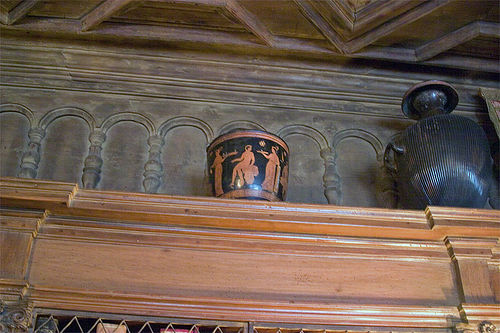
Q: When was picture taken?
A: Daytime.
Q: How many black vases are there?
A: One.